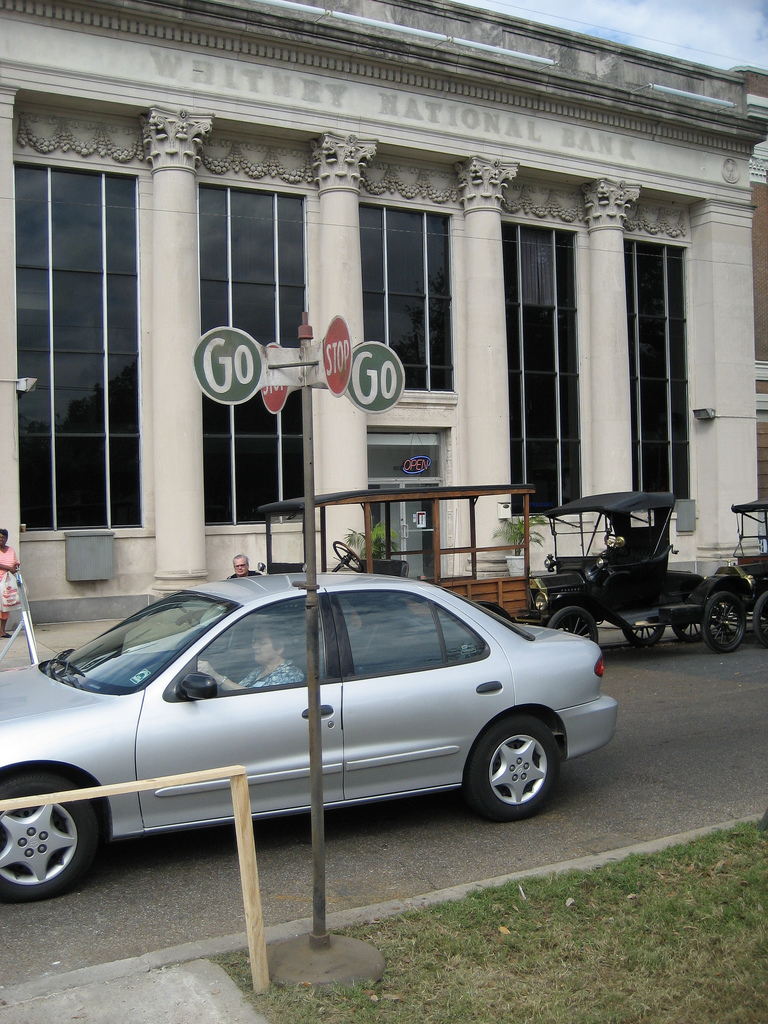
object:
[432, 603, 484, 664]
window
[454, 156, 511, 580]
column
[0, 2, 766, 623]
building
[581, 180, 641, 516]
column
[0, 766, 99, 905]
wheel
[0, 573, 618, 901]
car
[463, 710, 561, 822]
wheel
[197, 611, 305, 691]
driver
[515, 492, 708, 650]
antique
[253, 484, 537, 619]
antique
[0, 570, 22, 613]
bag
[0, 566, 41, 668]
hands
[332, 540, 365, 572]
steering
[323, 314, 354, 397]
street sign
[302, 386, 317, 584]
pole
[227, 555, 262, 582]
man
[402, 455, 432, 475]
neon sign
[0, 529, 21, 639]
woman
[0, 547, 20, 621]
dress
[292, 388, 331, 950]
post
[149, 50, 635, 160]
whitney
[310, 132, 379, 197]
signage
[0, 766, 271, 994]
fence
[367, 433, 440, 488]
glass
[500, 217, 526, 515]
frame